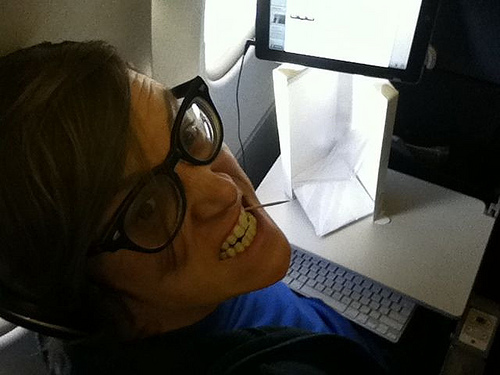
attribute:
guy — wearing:
[21, 15, 330, 372]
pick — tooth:
[222, 181, 302, 233]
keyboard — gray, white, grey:
[309, 293, 445, 336]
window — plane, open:
[216, 11, 249, 51]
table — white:
[368, 194, 488, 294]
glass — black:
[50, 47, 268, 298]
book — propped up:
[248, 44, 415, 208]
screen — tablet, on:
[248, 16, 424, 91]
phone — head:
[4, 275, 72, 345]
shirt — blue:
[217, 263, 383, 334]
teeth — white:
[204, 194, 267, 265]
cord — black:
[218, 26, 286, 150]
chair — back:
[6, 303, 131, 368]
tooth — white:
[192, 207, 272, 279]